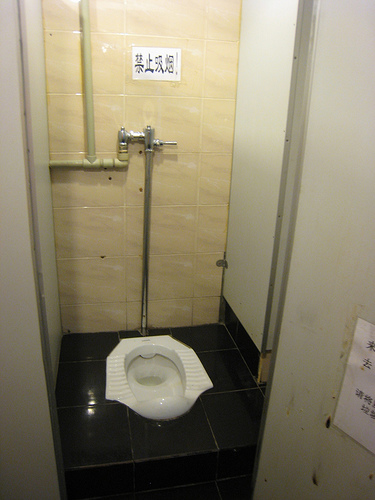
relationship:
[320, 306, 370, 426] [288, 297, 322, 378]
sign on wall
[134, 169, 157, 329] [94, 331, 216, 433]
piping behind toilet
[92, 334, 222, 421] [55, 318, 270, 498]
toilet on floor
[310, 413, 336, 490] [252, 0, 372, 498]
dirtymarks on wall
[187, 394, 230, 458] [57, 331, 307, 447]
line in floor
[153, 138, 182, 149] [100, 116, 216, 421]
handle of toilet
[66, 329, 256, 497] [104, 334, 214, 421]
floor around toilet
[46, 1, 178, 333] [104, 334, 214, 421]
plumbing to toilet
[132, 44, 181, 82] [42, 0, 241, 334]
sign on wall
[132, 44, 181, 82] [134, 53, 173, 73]
sign with black letters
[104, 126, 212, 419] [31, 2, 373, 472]
stall in restroom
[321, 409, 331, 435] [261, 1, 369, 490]
mark on door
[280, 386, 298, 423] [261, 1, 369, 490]
mark on door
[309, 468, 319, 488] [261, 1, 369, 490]
mark on door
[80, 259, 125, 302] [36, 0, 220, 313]
tile on wall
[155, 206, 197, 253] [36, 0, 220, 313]
tile on wall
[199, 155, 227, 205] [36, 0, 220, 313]
tile on wall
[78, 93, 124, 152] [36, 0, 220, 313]
tile on wall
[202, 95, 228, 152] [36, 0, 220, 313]
tile on wall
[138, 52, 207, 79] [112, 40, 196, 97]
lettering on sign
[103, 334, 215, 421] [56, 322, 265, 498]
toilet in floor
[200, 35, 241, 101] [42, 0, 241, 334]
tile of wall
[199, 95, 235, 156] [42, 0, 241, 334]
tile of wall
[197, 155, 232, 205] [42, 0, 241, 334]
tile of wall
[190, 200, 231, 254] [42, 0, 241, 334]
tile of wall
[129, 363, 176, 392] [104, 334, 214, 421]
water inside of toilet